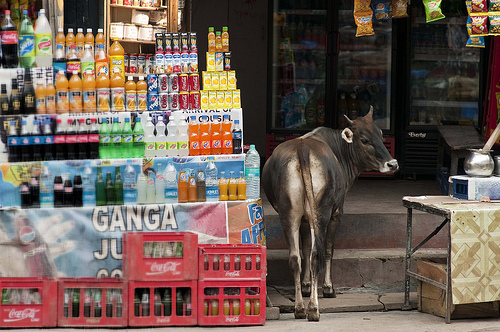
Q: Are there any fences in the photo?
A: No, there are no fences.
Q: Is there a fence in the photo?
A: No, there are no fences.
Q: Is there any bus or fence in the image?
A: No, there are no fences or buses.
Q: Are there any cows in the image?
A: Yes, there is a cow.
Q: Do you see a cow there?
A: Yes, there is a cow.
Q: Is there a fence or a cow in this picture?
A: Yes, there is a cow.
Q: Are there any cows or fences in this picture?
A: Yes, there is a cow.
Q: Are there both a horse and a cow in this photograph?
A: No, there is a cow but no horses.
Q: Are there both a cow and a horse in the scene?
A: No, there is a cow but no horses.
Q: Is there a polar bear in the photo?
A: No, there are no polar bears.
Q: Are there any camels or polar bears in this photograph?
A: No, there are no polar bears or camels.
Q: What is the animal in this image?
A: The animal is a cow.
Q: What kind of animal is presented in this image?
A: The animal is a cow.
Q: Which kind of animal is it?
A: The animal is a cow.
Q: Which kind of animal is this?
A: That is a cow.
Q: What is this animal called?
A: That is a cow.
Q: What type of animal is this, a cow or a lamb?
A: That is a cow.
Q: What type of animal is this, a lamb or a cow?
A: That is a cow.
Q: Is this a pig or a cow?
A: This is a cow.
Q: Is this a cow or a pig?
A: This is a cow.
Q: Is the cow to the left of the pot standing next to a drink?
A: Yes, the cow is standing next to a drink.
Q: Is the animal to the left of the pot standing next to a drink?
A: Yes, the cow is standing next to a drink.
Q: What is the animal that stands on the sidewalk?
A: The animal is a cow.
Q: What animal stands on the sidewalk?
A: The animal is a cow.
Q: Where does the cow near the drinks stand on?
A: The cow stands on the sidewalk.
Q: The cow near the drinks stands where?
A: The cow stands on the sidewalk.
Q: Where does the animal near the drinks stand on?
A: The cow stands on the sidewalk.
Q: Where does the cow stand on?
A: The cow stands on the sidewalk.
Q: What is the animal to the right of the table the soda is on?
A: The animal is a cow.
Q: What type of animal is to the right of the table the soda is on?
A: The animal is a cow.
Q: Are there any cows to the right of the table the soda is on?
A: Yes, there is a cow to the right of the table.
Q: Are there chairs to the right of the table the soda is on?
A: No, there is a cow to the right of the table.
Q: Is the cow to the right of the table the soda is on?
A: Yes, the cow is to the right of the table.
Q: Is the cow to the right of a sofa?
A: No, the cow is to the right of the table.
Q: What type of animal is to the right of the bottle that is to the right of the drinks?
A: The animal is a cow.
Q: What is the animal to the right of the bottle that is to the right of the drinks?
A: The animal is a cow.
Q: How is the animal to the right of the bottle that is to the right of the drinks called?
A: The animal is a cow.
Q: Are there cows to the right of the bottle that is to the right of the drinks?
A: Yes, there is a cow to the right of the bottle.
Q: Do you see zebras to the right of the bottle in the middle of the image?
A: No, there is a cow to the right of the bottle.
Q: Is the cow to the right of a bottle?
A: Yes, the cow is to the right of a bottle.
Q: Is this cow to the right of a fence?
A: No, the cow is to the right of a bottle.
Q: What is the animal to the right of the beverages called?
A: The animal is a cow.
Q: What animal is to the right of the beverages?
A: The animal is a cow.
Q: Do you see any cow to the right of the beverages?
A: Yes, there is a cow to the right of the beverages.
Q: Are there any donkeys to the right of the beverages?
A: No, there is a cow to the right of the beverages.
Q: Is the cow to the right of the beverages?
A: Yes, the cow is to the right of the beverages.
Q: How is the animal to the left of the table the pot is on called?
A: The animal is a cow.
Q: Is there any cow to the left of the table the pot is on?
A: Yes, there is a cow to the left of the table.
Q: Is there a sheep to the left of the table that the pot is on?
A: No, there is a cow to the left of the table.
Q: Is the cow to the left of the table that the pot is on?
A: Yes, the cow is to the left of the table.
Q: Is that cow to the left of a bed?
A: No, the cow is to the left of the table.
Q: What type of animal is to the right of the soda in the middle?
A: The animal is a cow.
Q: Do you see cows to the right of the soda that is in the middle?
A: Yes, there is a cow to the right of the soda.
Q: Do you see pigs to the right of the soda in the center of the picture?
A: No, there is a cow to the right of the soda.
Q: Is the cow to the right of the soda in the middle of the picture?
A: Yes, the cow is to the right of the soda.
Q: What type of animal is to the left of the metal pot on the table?
A: The animal is a cow.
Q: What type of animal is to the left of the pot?
A: The animal is a cow.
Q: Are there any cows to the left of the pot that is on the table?
A: Yes, there is a cow to the left of the pot.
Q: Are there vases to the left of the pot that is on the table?
A: No, there is a cow to the left of the pot.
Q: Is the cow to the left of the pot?
A: Yes, the cow is to the left of the pot.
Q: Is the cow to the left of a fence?
A: No, the cow is to the left of the pot.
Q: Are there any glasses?
A: No, there are no glasses.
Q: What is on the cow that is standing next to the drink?
A: The soda is on the cow.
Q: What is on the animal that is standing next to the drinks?
A: The soda is on the cow.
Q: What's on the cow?
A: The soda is on the cow.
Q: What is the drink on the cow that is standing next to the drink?
A: The drink is soda.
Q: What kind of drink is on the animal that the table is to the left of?
A: The drink is soda.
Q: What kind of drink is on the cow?
A: The drink is soda.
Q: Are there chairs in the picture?
A: No, there are no chairs.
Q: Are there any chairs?
A: No, there are no chairs.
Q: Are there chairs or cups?
A: No, there are no chairs or cups.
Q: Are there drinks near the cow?
A: Yes, there are drinks near the cow.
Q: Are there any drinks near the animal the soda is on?
A: Yes, there are drinks near the cow.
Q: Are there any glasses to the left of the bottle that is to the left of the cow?
A: No, there are drinks to the left of the bottle.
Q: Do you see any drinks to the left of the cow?
A: Yes, there are drinks to the left of the cow.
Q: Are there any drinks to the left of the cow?
A: Yes, there are drinks to the left of the cow.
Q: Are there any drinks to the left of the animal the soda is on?
A: Yes, there are drinks to the left of the cow.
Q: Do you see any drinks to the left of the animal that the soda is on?
A: Yes, there are drinks to the left of the cow.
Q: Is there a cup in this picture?
A: No, there are no cups.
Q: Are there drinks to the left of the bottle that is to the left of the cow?
A: Yes, there are drinks to the left of the bottle.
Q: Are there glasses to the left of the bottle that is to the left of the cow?
A: No, there are drinks to the left of the bottle.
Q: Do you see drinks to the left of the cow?
A: Yes, there are drinks to the left of the cow.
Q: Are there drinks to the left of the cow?
A: Yes, there are drinks to the left of the cow.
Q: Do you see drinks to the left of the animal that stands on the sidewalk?
A: Yes, there are drinks to the left of the cow.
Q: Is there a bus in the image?
A: No, there are no buses.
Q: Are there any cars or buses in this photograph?
A: No, there are no buses or cars.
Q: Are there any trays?
A: No, there are no trays.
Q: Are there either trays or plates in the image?
A: No, there are no trays or plates.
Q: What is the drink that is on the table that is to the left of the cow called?
A: The drink is soda.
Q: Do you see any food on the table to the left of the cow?
A: No, there is soda on the table.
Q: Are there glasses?
A: No, there are no glasses.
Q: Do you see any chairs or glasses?
A: No, there are no glasses or chairs.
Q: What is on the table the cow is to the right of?
A: The soda is on the table.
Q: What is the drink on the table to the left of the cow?
A: The drink is soda.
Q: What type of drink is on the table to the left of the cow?
A: The drink is soda.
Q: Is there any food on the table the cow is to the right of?
A: No, there is soda on the table.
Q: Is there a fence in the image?
A: No, there are no fences.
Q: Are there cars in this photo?
A: No, there are no cars.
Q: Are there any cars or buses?
A: No, there are no cars or buses.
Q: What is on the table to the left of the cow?
A: The soda is on the table.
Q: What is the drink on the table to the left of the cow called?
A: The drink is soda.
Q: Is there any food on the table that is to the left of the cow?
A: No, there is soda on the table.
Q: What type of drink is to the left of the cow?
A: The drink is soda.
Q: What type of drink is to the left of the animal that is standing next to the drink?
A: The drink is soda.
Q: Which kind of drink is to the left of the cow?
A: The drink is soda.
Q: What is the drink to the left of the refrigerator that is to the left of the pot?
A: The drink is soda.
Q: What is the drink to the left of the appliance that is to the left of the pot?
A: The drink is soda.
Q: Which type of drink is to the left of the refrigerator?
A: The drink is soda.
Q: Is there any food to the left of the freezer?
A: No, there is soda to the left of the freezer.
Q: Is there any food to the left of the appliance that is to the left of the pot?
A: No, there is soda to the left of the freezer.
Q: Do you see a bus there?
A: No, there are no buses.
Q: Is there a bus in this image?
A: No, there are no buses.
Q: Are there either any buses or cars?
A: No, there are no buses or cars.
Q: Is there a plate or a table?
A: Yes, there is a table.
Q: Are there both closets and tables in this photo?
A: No, there is a table but no closets.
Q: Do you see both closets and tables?
A: No, there is a table but no closets.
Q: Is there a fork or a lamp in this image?
A: No, there are no forks or lamps.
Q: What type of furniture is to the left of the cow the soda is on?
A: The piece of furniture is a table.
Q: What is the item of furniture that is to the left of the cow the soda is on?
A: The piece of furniture is a table.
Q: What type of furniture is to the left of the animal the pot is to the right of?
A: The piece of furniture is a table.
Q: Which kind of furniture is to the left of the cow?
A: The piece of furniture is a table.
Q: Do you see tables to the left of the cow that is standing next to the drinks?
A: Yes, there is a table to the left of the cow.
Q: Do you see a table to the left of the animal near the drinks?
A: Yes, there is a table to the left of the cow.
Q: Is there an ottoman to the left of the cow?
A: No, there is a table to the left of the cow.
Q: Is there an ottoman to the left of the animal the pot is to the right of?
A: No, there is a table to the left of the cow.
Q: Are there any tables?
A: Yes, there is a table.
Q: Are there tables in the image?
A: Yes, there is a table.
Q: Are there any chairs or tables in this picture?
A: Yes, there is a table.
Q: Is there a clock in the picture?
A: No, there are no clocks.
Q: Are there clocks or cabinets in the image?
A: No, there are no clocks or cabinets.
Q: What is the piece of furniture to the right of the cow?
A: The piece of furniture is a table.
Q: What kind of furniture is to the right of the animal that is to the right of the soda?
A: The piece of furniture is a table.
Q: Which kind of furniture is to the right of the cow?
A: The piece of furniture is a table.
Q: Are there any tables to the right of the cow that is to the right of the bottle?
A: Yes, there is a table to the right of the cow.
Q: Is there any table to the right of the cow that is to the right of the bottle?
A: Yes, there is a table to the right of the cow.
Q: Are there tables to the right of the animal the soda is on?
A: Yes, there is a table to the right of the cow.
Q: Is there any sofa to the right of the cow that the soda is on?
A: No, there is a table to the right of the cow.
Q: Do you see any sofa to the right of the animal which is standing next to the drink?
A: No, there is a table to the right of the cow.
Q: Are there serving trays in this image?
A: No, there are no serving trays.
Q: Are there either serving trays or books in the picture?
A: No, there are no serving trays or books.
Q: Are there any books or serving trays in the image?
A: No, there are no serving trays or books.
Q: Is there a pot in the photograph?
A: Yes, there is a pot.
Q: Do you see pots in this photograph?
A: Yes, there is a pot.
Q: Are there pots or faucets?
A: Yes, there is a pot.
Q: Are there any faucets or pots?
A: Yes, there is a pot.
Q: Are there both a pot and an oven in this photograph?
A: No, there is a pot but no ovens.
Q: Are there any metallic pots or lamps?
A: Yes, there is a metal pot.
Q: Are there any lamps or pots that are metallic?
A: Yes, the pot is metallic.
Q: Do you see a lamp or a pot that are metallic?
A: Yes, the pot is metallic.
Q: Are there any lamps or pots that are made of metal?
A: Yes, the pot is made of metal.